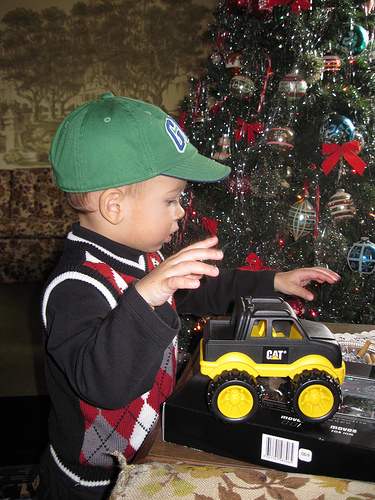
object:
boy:
[34, 83, 344, 499]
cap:
[47, 83, 234, 199]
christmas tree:
[154, 3, 374, 373]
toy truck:
[199, 295, 347, 424]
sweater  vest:
[31, 225, 186, 488]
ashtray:
[335, 337, 375, 377]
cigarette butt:
[356, 340, 372, 360]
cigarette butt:
[366, 353, 374, 365]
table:
[134, 321, 374, 465]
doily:
[333, 328, 374, 342]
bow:
[319, 139, 368, 176]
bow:
[233, 114, 265, 145]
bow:
[237, 251, 274, 271]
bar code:
[260, 432, 299, 469]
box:
[159, 371, 375, 484]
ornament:
[265, 125, 299, 153]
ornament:
[347, 237, 375, 277]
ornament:
[230, 74, 256, 105]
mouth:
[167, 228, 181, 244]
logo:
[266, 348, 288, 361]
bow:
[262, 1, 316, 14]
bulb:
[285, 192, 316, 242]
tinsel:
[236, 175, 240, 192]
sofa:
[108, 455, 375, 499]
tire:
[206, 371, 260, 423]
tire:
[288, 368, 343, 424]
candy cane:
[257, 51, 271, 113]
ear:
[98, 188, 126, 226]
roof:
[242, 294, 297, 318]